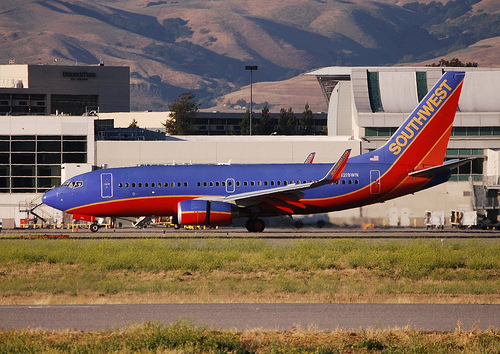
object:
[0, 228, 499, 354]
land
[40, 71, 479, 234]
airplane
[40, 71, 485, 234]
airplane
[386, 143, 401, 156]
letters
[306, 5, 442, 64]
mountain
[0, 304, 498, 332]
tarmac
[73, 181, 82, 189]
window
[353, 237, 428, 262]
weeds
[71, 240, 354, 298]
dirt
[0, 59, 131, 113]
building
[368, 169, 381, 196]
exit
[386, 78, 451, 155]
name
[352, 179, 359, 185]
windows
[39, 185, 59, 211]
nose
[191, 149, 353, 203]
wing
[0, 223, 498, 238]
runway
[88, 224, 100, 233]
wheel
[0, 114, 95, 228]
building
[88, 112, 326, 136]
building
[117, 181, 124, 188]
windows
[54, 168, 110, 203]
cockpit